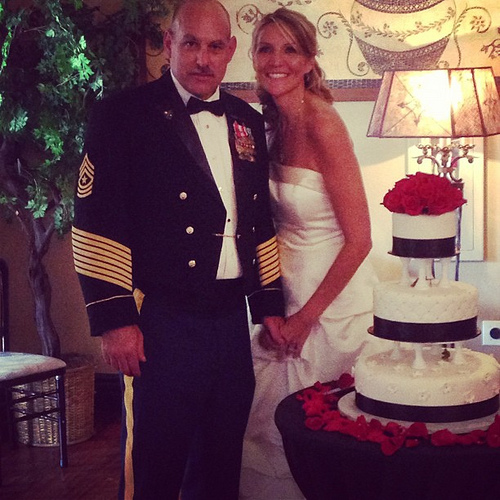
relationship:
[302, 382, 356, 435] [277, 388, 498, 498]
petals on table cloth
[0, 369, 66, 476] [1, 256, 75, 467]
legs of chair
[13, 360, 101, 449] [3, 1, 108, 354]
basket with tree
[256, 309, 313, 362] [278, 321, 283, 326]
hands being held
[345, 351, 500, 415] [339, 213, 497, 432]
tier of cake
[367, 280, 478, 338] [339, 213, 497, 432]
tier of cake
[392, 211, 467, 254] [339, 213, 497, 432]
tier of cake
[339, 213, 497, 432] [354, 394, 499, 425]
cake with trimming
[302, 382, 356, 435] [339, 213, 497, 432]
petals around cake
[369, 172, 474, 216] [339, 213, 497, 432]
roses on top of cake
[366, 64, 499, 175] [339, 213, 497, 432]
lamp behind cake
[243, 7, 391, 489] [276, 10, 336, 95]
bride with hair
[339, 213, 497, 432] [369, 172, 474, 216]
cake with rose topping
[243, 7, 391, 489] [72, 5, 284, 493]
bride and groom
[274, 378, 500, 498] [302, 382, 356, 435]
table with petals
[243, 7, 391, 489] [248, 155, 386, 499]
woman in wedding dress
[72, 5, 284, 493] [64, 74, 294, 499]
man in uniform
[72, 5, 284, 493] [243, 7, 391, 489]
man and woman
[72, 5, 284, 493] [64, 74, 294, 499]
man wearing uniform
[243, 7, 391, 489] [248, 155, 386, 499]
woman wearing wedding dress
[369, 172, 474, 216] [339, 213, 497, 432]
flowers on top of cake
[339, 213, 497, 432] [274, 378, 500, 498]
wedding cake on table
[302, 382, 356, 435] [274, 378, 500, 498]
petals on table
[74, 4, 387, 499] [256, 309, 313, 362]
couple holding hands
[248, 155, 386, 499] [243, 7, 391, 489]
dress on woman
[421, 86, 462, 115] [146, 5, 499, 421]
light on wall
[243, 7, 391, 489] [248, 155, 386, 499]
woman wearing dress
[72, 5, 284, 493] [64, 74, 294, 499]
man wearing suit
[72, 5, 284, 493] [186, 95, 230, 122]
man wearing bow tie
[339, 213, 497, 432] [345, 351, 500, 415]
cake with tier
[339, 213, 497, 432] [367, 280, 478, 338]
cake with tier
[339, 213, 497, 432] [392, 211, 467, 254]
cake with tier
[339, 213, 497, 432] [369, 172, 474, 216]
cake with flowers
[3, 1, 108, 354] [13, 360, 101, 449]
tree in basket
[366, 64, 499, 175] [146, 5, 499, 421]
lamp on wall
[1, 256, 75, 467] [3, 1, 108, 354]
chair next to tree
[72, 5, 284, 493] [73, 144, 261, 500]
groom wearing a uniform